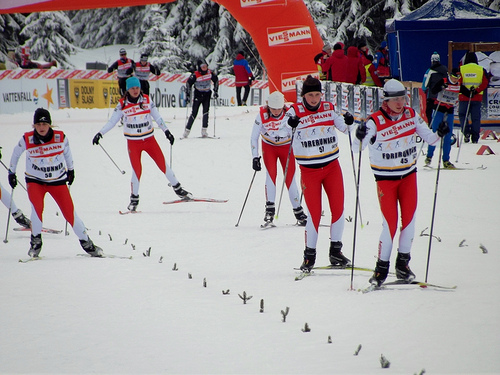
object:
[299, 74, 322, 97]
beanie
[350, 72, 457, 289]
person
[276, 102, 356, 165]
shirt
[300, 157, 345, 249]
pants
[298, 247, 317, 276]
shoe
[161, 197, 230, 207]
ski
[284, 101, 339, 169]
vest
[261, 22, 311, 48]
sign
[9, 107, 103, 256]
competitor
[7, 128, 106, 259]
uniform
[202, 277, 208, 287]
divider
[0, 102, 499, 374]
snow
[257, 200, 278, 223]
foot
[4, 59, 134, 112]
barrier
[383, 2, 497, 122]
tent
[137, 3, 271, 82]
tree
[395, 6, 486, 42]
roof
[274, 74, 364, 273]
people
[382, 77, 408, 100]
hat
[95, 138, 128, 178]
pole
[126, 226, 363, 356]
line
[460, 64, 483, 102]
vest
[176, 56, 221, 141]
skier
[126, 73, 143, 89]
cap